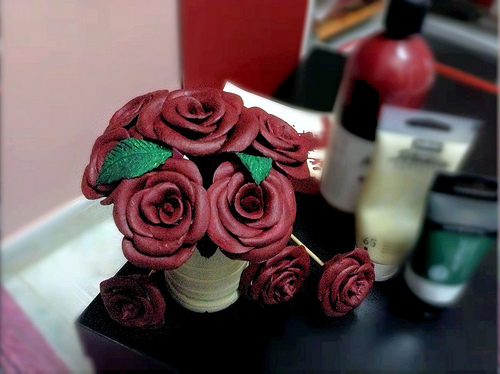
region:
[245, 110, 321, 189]
red rose in vase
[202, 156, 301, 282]
red rose in vase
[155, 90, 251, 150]
red rose in vase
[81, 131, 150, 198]
red rose in vase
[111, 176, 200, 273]
red rose in vase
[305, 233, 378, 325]
red rose next to vase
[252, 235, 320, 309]
red rose next to vase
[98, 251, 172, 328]
red rose next to vase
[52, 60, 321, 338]
bouquet of red roses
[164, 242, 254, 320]
white vase on table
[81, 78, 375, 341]
Artful painted flowers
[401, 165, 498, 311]
Tube of dark green paint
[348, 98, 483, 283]
Tube of off white paint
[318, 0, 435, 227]
Bottle of red paint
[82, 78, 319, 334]
Small handmade bouquet of clay roses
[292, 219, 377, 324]
Clay rose with attached toothpick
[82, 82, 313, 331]
Clay bouquet of red roses with green leaves in offwhite pot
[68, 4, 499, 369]
Small clay pot of red roses sits on a table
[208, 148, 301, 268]
Handmade rose made of clay and painted red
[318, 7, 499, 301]
Red, cream and forest green artist paints.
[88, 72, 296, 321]
Roses in a vase.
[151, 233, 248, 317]
white vase on the table.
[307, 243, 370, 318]
Red colored rose on the table.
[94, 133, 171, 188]
Green leaf in the bouquet.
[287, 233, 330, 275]
Stick stem on the flower.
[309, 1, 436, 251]
Red bottle on the table.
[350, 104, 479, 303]
yellow tube on the table.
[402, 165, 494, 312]
Green and black tube on the table.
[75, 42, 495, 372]
Black table in the forefront.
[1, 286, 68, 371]
Pink rug on the floor.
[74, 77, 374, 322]
the roses are red.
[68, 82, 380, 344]
the roses are fake.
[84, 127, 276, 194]
two leaves in the roses.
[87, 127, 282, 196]
the leaves are green.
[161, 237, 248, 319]
the vase is white.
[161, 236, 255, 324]
vase sitting on the table.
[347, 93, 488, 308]
lotion on the table.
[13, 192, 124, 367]
the floor is white.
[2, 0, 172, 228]
the wall is pink.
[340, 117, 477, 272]
the lotion is white.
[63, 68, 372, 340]
a bouquet of roses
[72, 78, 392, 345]
the flowers are molded from clay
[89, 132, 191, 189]
the leaf is green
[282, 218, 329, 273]
a wooden toothpick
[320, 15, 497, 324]
bottles of paint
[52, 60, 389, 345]
this was hand painted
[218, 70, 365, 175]
a white piece of scratch paper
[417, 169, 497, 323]
this is green paint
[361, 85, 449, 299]
this bottle is the pastel yellow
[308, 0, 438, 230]
a bottle of red paint